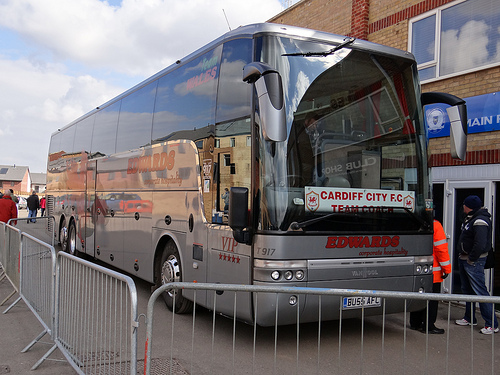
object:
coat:
[429, 220, 452, 284]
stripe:
[433, 239, 447, 247]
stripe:
[439, 259, 450, 267]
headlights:
[270, 270, 281, 281]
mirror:
[445, 106, 466, 161]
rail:
[2, 280, 499, 372]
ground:
[0, 222, 500, 375]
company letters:
[326, 237, 338, 248]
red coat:
[0, 195, 18, 226]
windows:
[407, 0, 496, 87]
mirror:
[229, 186, 250, 231]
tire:
[59, 218, 69, 252]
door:
[205, 131, 257, 292]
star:
[219, 253, 223, 260]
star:
[223, 253, 227, 260]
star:
[227, 254, 231, 262]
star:
[232, 255, 236, 263]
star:
[236, 256, 241, 264]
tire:
[158, 239, 195, 316]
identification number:
[262, 248, 268, 255]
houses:
[0, 165, 33, 206]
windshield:
[253, 30, 433, 233]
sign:
[303, 186, 417, 217]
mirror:
[255, 72, 288, 143]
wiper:
[280, 37, 356, 58]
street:
[2, 200, 499, 373]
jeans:
[458, 260, 498, 326]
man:
[410, 218, 452, 335]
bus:
[44, 22, 435, 332]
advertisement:
[304, 186, 416, 214]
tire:
[68, 219, 77, 255]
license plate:
[344, 297, 381, 309]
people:
[0, 189, 18, 227]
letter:
[352, 298, 356, 306]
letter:
[366, 297, 370, 304]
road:
[8, 213, 481, 356]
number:
[348, 299, 351, 306]